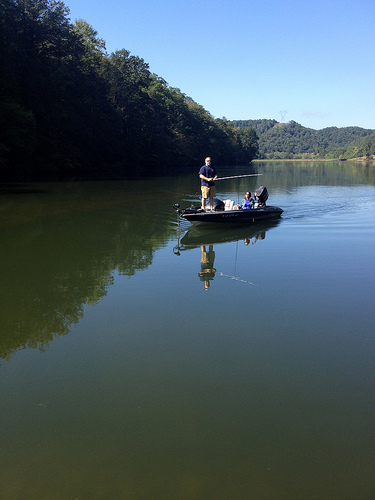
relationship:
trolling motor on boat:
[253, 184, 269, 203] [180, 200, 284, 221]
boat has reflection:
[180, 200, 284, 221] [181, 216, 283, 248]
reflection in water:
[181, 216, 283, 248] [0, 159, 372, 500]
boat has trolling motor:
[180, 200, 284, 221] [253, 184, 269, 203]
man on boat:
[199, 155, 216, 213] [180, 200, 284, 221]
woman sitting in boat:
[241, 191, 255, 210] [180, 200, 284, 221]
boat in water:
[180, 200, 284, 221] [0, 159, 372, 500]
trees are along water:
[1, 1, 258, 172] [0, 159, 372, 500]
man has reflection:
[199, 155, 216, 213] [198, 244, 217, 290]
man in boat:
[199, 155, 216, 213] [180, 200, 284, 221]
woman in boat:
[241, 191, 255, 210] [180, 200, 284, 221]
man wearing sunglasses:
[199, 155, 216, 213] [205, 159, 213, 164]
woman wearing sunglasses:
[241, 191, 255, 210] [245, 193, 251, 198]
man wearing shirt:
[199, 155, 216, 213] [198, 165, 217, 186]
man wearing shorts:
[199, 155, 216, 213] [200, 185, 215, 199]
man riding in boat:
[199, 155, 216, 213] [180, 200, 284, 221]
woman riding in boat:
[241, 191, 255, 210] [180, 200, 284, 221]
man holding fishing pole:
[199, 155, 216, 213] [214, 172, 263, 182]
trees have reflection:
[1, 1, 258, 172] [1, 167, 213, 358]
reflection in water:
[1, 167, 213, 358] [0, 159, 372, 500]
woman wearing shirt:
[241, 191, 255, 210] [241, 200, 254, 208]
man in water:
[199, 155, 216, 213] [0, 159, 372, 500]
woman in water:
[241, 191, 255, 210] [0, 159, 372, 500]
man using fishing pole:
[199, 155, 216, 213] [214, 172, 263, 182]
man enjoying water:
[199, 155, 216, 213] [0, 159, 372, 500]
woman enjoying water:
[241, 191, 255, 210] [0, 159, 372, 500]